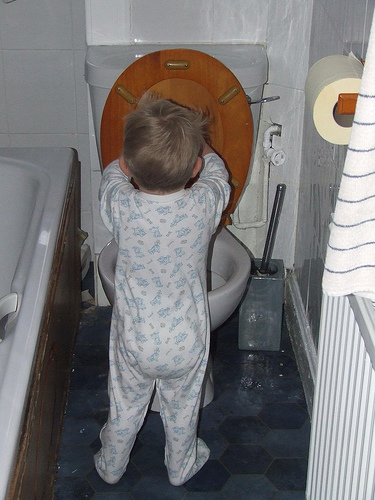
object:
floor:
[57, 302, 312, 499]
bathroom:
[1, 0, 374, 497]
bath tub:
[0, 147, 87, 499]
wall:
[293, 1, 374, 353]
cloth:
[322, 7, 375, 302]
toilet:
[84, 42, 268, 413]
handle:
[244, 94, 280, 107]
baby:
[94, 91, 231, 489]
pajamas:
[93, 153, 232, 487]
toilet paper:
[305, 50, 365, 145]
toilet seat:
[100, 47, 252, 226]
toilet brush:
[254, 185, 285, 277]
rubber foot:
[164, 60, 191, 71]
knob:
[270, 149, 286, 166]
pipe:
[233, 124, 286, 230]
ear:
[191, 157, 203, 182]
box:
[237, 257, 285, 351]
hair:
[121, 90, 212, 195]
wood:
[12, 159, 82, 499]